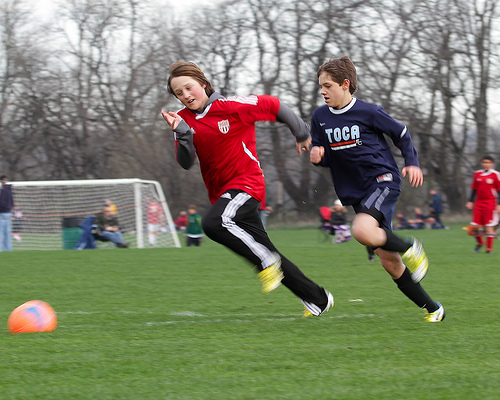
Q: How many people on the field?
A: Two.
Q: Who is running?
A: The boys.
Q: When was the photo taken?
A: Day time.